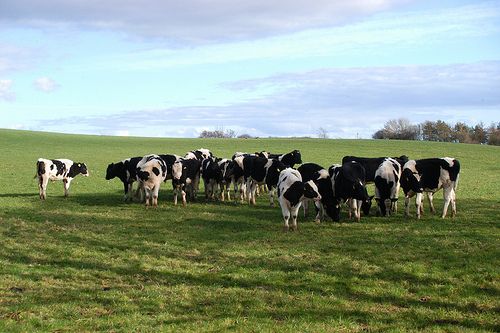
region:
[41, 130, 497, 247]
the cows are black and white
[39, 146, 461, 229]
the cows are together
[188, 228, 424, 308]
tree shadow is on the ground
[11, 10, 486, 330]
the picture was taken during the day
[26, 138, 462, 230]
the cows are grazing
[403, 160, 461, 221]
the cow is lokking to the right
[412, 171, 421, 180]
white spot is head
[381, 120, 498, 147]
trees are in the background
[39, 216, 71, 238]
brown patch of grass is on the ground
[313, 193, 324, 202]
the nose is pink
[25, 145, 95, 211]
a cow standing on a field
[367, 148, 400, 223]
a cow standing on a field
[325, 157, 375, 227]
a cow standing on a field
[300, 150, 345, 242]
a cow standing on a field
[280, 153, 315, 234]
a cow standing on a field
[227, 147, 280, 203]
a cow standing on a field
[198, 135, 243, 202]
a cow standing on a field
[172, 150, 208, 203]
a cow standing on a field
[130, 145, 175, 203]
a cow standing on a field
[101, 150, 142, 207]
a cow standing on a field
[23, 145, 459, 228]
Herd of cattle on the grass.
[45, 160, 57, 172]
black spot on the cow.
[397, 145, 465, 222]
back and white cow.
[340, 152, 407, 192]
black cow in the background.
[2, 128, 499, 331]
Green grass covering the ground.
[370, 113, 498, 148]
Trees in the background.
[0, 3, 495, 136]
Gray and white clouds in the sky.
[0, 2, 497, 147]
blue sky in the background.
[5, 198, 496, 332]
shadows on the grass.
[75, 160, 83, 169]
Tag on cow's ear.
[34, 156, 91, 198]
a cow in a field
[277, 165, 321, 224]
cow is black and white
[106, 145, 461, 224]
a group of cows in a field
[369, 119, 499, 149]
trees in the distance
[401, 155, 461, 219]
a cow is in a field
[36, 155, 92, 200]
cow is black and white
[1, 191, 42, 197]
shadow of a cow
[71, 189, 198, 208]
shadow of cows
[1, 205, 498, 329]
shadows on grass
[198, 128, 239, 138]
branches of a tree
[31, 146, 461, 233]
A small herd of cattle.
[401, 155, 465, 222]
A black and white cow.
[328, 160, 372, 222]
A cow with a black head.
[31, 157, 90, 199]
A cow standing alone.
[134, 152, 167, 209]
A cow with black spots.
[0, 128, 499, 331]
A large area of grazing land.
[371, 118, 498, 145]
A grouping of trees.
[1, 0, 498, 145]
A background of sky.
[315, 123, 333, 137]
A large distant tree.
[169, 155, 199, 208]
A cow with a white and black head.